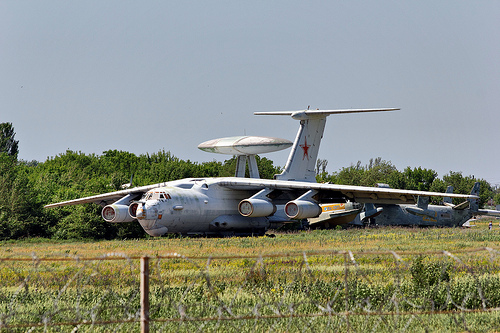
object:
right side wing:
[44, 181, 169, 223]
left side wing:
[219, 176, 481, 219]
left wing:
[323, 108, 401, 114]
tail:
[273, 116, 329, 182]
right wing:
[253, 111, 291, 115]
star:
[299, 136, 311, 161]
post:
[139, 255, 149, 332]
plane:
[44, 105, 481, 237]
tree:
[0, 121, 500, 242]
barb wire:
[0, 245, 499, 331]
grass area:
[5, 212, 499, 333]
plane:
[348, 182, 488, 226]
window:
[160, 194, 165, 198]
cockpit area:
[142, 191, 171, 200]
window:
[142, 193, 146, 198]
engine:
[237, 188, 277, 218]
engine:
[283, 189, 322, 220]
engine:
[101, 194, 138, 223]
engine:
[127, 200, 140, 219]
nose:
[127, 201, 145, 219]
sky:
[0, 0, 498, 166]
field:
[0, 223, 496, 333]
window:
[148, 193, 153, 200]